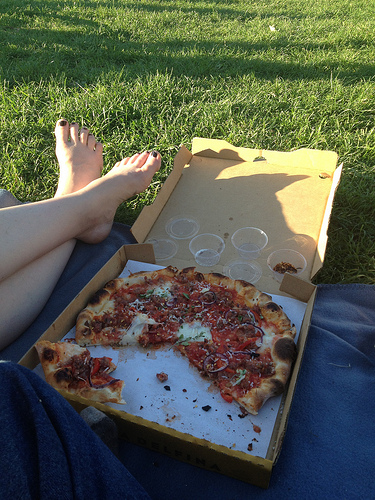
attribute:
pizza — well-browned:
[255, 297, 294, 386]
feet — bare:
[44, 111, 165, 245]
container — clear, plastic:
[232, 227, 271, 259]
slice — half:
[21, 341, 134, 406]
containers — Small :
[190, 234, 223, 260]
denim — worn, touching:
[2, 394, 74, 480]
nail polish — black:
[60, 121, 66, 125]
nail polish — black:
[150, 151, 156, 157]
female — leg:
[1, 84, 111, 255]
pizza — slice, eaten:
[171, 261, 238, 384]